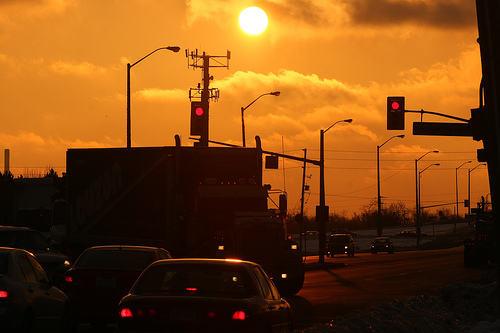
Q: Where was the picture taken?
A: The road.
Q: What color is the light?
A: Red.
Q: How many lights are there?
A: Two.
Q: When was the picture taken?
A: Sunset.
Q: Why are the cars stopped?
A: It is a red light.